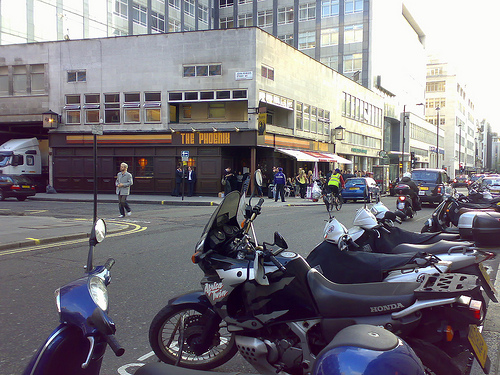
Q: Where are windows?
A: On buildings.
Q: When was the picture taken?
A: Daytime.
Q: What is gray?
A: The road.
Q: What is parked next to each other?
A: Motorcycles.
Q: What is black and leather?
A: Motorbike seats.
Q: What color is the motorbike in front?
A: Blue.